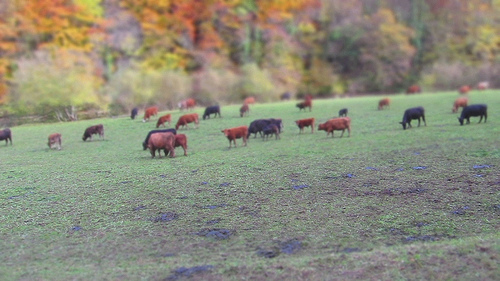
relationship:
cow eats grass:
[147, 133, 179, 158] [56, 158, 152, 237]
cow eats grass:
[159, 129, 191, 156] [23, 117, 80, 168]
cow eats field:
[83, 125, 105, 144] [0, 90, 497, 281]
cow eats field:
[396, 98, 430, 128] [0, 90, 497, 281]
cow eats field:
[458, 104, 489, 127] [0, 90, 497, 281]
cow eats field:
[231, 100, 253, 115] [0, 90, 497, 281]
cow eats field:
[46, 130, 65, 148] [0, 90, 497, 281]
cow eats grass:
[247, 118, 283, 139] [230, 153, 386, 235]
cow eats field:
[399, 104, 428, 128] [0, 90, 497, 281]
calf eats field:
[317, 117, 350, 139] [0, 90, 497, 281]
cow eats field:
[221, 126, 253, 148] [0, 90, 497, 281]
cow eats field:
[142, 103, 159, 121] [0, 90, 497, 281]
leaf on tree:
[78, 5, 85, 10] [219, 1, 304, 66]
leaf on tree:
[143, 8, 148, 12] [219, 1, 304, 66]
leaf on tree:
[188, 19, 193, 24] [219, 1, 304, 66]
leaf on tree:
[185, 21, 190, 24] [219, 1, 304, 66]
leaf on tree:
[207, 30, 210, 33] [219, 1, 304, 66]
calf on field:
[324, 109, 354, 139] [0, 90, 497, 281]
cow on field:
[147, 133, 179, 158] [0, 90, 497, 281]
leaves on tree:
[397, 24, 431, 71] [385, 26, 437, 81]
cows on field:
[129, 96, 421, 158] [1, 82, 497, 277]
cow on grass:
[458, 104, 489, 127] [2, 151, 498, 280]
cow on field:
[147, 133, 179, 158] [1, 82, 497, 277]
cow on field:
[398, 106, 427, 130] [1, 82, 497, 277]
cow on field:
[458, 104, 489, 127] [1, 82, 497, 277]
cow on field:
[83, 120, 102, 139] [1, 82, 497, 277]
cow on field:
[201, 105, 222, 120] [1, 82, 497, 277]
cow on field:
[458, 104, 489, 127] [0, 90, 497, 281]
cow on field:
[146, 129, 178, 159] [1, 82, 497, 277]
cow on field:
[223, 124, 250, 149] [1, 82, 497, 277]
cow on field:
[248, 117, 280, 138] [1, 82, 497, 277]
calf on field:
[317, 117, 350, 139] [1, 82, 497, 277]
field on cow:
[1, 82, 497, 277] [458, 104, 489, 127]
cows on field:
[216, 121, 248, 145] [1, 82, 497, 277]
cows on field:
[314, 118, 351, 140] [1, 82, 497, 277]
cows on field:
[398, 105, 429, 132] [1, 82, 497, 277]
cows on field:
[453, 103, 488, 120] [1, 82, 497, 277]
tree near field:
[0, 0, 500, 128] [1, 82, 497, 277]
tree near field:
[73, 0, 135, 117] [1, 82, 497, 277]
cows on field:
[404, 107, 440, 136] [1, 82, 497, 277]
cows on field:
[319, 109, 364, 143] [1, 82, 497, 277]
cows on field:
[137, 125, 188, 158] [1, 82, 497, 277]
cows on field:
[452, 104, 497, 127] [1, 82, 497, 277]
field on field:
[0, 90, 497, 281] [1, 82, 497, 277]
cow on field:
[202, 105, 221, 118] [0, 90, 497, 281]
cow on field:
[82, 123, 105, 141] [0, 90, 497, 281]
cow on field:
[397, 106, 427, 128] [0, 90, 497, 281]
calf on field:
[317, 117, 350, 139] [0, 90, 497, 281]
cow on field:
[221, 127, 248, 147] [0, 90, 497, 281]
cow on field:
[459, 103, 486, 123] [1, 82, 497, 277]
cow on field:
[221, 128, 246, 148] [1, 82, 497, 277]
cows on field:
[1, 75, 492, 164] [0, 90, 497, 281]